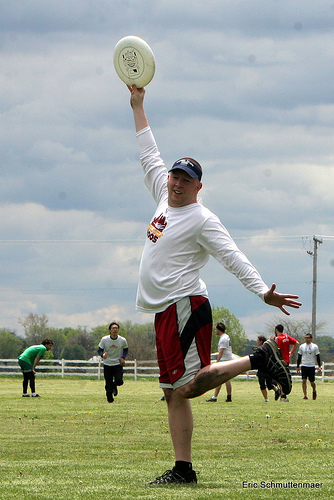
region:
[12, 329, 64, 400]
A tired man in green shirt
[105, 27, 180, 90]
A white frisbee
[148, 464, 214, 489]
Black Sport Shoes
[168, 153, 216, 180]
A visor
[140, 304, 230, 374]
Red Shorts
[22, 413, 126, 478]
Green Grass on a field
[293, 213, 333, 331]
a electricity pole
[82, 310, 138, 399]
A man running towards the man with frisbee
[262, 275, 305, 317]
A man's hand spread out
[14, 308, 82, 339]
Trees in the background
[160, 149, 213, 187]
Black cap on man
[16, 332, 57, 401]
Man in green shirt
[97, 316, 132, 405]
Man in white shirt running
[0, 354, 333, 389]
White fence line in the back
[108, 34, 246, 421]
Man posing with frisbee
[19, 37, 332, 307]
Blue, cloudy skies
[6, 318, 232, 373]
Trees on outside of the fence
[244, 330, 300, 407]
Black muddy sneakers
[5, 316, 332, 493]
Green grassy mowed field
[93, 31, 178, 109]
White frisbee being held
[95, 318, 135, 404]
A man running on the field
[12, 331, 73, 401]
A man in a green shirt hunched over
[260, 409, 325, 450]
Dandelions in the field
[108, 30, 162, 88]
White frisbee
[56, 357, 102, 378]
White fence in the background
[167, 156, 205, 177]
A blue visor on a man's head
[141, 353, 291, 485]
Muddy legs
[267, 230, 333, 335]
Power lines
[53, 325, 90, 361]
Various types of trees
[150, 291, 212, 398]
A pair of red, black, and white shorts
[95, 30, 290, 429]
Man catching a white flying disc.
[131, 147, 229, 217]
Man wearing blue visor.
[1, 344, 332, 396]
White wooden fence.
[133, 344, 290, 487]
Mud on a person's left leg.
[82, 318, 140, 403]
Man wearing a t-shirt over a long sleeved shirt.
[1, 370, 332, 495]
Large field with short grass and dandelions.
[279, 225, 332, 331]
Tall wooden telephone pole.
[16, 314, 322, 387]
Line of trees.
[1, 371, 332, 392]
Tall grass at the base of a fence.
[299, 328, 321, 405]
Man wearing a white shirt and black shorts.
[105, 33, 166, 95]
hand holding a frisbee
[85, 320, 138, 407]
a man running fast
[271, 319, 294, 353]
man wearing a red shirt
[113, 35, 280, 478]
man posing with a frisbee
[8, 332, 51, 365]
man wearing a green shirt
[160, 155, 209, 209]
man wearing a blue cap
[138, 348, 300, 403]
bent leg with black shoe on foot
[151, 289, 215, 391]
red, white, and blue shorts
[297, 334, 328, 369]
man wearing a white shirt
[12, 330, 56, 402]
a man bending over